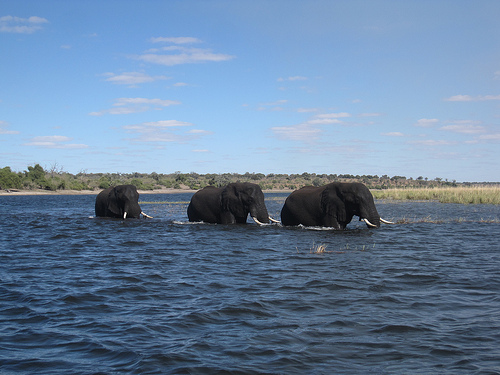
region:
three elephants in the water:
[75, 168, 402, 244]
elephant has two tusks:
[357, 207, 397, 228]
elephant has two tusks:
[248, 207, 278, 225]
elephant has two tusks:
[116, 205, 151, 220]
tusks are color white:
[360, 210, 400, 230]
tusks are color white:
[250, 210, 280, 228]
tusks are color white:
[114, 208, 153, 223]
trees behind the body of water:
[0, 163, 499, 205]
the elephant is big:
[270, 176, 402, 236]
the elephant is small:
[93, 180, 158, 230]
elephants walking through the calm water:
[76, 168, 411, 249]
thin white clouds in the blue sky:
[132, 23, 236, 73]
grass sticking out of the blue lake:
[291, 234, 388, 263]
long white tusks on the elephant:
[357, 215, 397, 233]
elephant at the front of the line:
[280, 173, 404, 248]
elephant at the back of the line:
[79, 173, 169, 229]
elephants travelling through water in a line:
[82, 176, 424, 241]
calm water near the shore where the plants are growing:
[10, 154, 80, 229]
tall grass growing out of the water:
[412, 161, 489, 256]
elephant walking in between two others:
[181, 178, 282, 236]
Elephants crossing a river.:
[86, 179, 403, 240]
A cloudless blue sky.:
[238, 0, 497, 77]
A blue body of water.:
[8, 268, 498, 374]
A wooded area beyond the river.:
[3, 163, 496, 191]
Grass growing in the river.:
[380, 183, 499, 233]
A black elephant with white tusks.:
[181, 175, 280, 230]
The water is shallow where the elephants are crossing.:
[69, 173, 436, 240]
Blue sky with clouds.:
[6, 64, 498, 177]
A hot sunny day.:
[6, 3, 496, 373]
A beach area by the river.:
[2, 183, 293, 195]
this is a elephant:
[78, 165, 150, 253]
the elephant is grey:
[85, 170, 164, 237]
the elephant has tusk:
[112, 202, 160, 230]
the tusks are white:
[116, 199, 160, 232]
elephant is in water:
[274, 155, 422, 292]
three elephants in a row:
[73, 158, 393, 259]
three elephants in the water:
[54, 150, 460, 327]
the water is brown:
[48, 220, 450, 351]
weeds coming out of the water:
[291, 225, 376, 272]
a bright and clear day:
[19, 13, 497, 361]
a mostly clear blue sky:
[5, 7, 487, 174]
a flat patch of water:
[12, 196, 482, 367]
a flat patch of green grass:
[374, 171, 491, 216]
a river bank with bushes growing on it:
[9, 160, 484, 204]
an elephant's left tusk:
[357, 218, 382, 229]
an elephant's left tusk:
[241, 210, 266, 227]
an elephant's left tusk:
[118, 210, 130, 224]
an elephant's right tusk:
[135, 205, 157, 222]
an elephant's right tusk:
[371, 212, 402, 229]